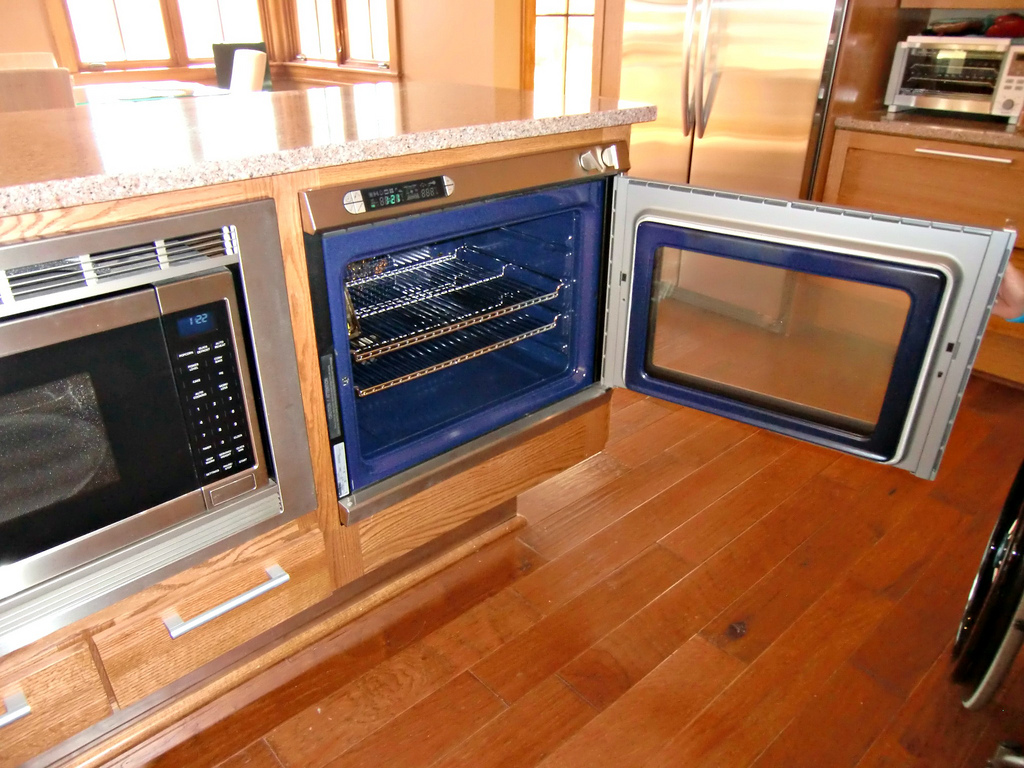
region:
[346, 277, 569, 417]
racks inside of the oven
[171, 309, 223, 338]
clock on the microwave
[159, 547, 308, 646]
handle of the drawer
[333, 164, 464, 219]
clock above the stove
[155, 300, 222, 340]
Blue display on the front of microwave.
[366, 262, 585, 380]
Three silver racks in the oven.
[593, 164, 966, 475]
Open door to the side of the oven.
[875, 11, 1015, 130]
Silver toaster oven on the counter.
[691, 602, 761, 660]
Big brown spot on the ground.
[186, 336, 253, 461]
White letters on the top of the buttons.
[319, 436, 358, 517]
White stickers on the side of the oven.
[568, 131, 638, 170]
Two knobs to the right of the oven.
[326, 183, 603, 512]
A blue shiny oven.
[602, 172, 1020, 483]
a open door on a oven.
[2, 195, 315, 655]
a stainless steel microwave.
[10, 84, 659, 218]
A grainate counter top.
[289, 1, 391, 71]
A pair of windows .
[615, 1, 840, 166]
A stainless steel refrigerator.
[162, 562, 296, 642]
A silver handle on a drawer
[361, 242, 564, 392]
Metal racks in a oven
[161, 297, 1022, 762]
hard wood floor panels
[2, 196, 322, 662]
a silver microwave oven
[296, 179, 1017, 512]
a oven with a blue inside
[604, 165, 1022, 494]
the door of a oven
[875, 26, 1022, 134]
a white toaster oven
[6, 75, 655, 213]
a stone marble counter top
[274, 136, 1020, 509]
shelf racks inside a oven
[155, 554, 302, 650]
a white draw handle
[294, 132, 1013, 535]
convection oven with open door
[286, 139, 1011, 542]
convection oven with blue interior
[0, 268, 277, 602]
silver and black microwave oven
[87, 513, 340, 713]
wooden drawer with metal handle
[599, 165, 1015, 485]
oven door in white and blue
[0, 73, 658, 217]
thick stone countertop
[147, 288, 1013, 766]
polished wood flooring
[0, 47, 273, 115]
white chair at dining table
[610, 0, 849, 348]
refrigerator with aluminum doors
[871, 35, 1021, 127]
white toaster oven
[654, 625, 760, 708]
the wooden floor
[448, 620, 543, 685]
a brown floor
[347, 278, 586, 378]
racks in the oven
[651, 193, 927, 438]
the oven door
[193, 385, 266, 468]
buttons on the microwave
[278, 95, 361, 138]
the countertop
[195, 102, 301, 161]
reflection on the counter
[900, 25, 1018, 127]
a toaster oven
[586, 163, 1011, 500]
oven door is open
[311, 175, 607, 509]
inside of oven is blue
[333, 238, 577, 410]
racks in oven are silver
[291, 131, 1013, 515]
oven under counter top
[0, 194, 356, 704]
microwave under counter top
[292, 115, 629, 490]
trey and blue colored oven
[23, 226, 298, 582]
black and silver colored microwave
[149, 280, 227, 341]
time on microwave that says 1:22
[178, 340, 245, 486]
white and black colored buttons on microwave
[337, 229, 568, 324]
metal tray in the oven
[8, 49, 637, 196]
granite counter top in the middle of the kitchen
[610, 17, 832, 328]
stainless steel fridge in the back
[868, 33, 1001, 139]
white colored toaster oven in the back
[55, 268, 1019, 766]
wooden floor paneling on the ground